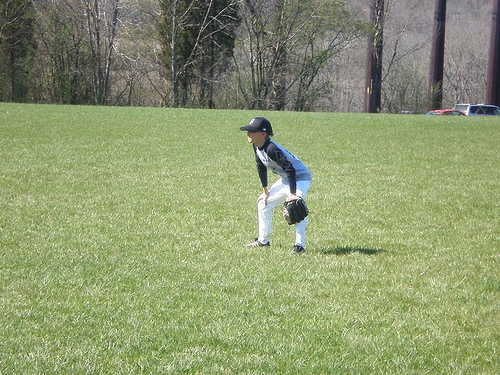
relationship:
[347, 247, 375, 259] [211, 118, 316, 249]
shadow of kid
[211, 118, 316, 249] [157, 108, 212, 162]
boy in field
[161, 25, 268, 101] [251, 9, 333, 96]
tree with no